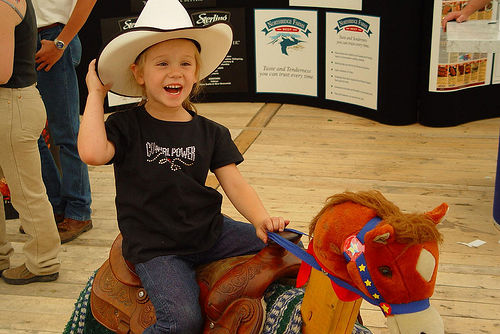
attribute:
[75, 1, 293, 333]
boy — riding, smiling, happy, dressed as cowboy, sitting, young, little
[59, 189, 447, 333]
pony — ride on, toy, fake, stuffed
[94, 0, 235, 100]
hat — cowboy hat, white, black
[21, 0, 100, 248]
man — standing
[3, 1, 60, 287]
woman — standing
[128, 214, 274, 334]
jeans — blue, childs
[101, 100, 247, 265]
shirt — black, printed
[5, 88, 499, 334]
floor — hardwood, wooden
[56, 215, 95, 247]
shoe — brown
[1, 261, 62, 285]
shoe — brown, black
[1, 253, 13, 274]
shoe — brown, black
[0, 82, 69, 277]
pants — tan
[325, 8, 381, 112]
promotional sign — white, paper, hanging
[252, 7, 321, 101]
promotional sign — white, hanging, paper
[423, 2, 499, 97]
sign — paper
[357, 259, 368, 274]
star — yellow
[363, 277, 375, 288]
star — yellow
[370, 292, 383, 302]
star — yellow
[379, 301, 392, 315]
star — yellow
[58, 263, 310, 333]
blanket — patterned, green, white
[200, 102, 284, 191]
stripe — brown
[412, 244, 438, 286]
diamond — white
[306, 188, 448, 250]
mane — tan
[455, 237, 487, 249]
garbage — white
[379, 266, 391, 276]
eye — glass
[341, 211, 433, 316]
bridle — blue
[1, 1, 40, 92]
shirt — black, sleeveless